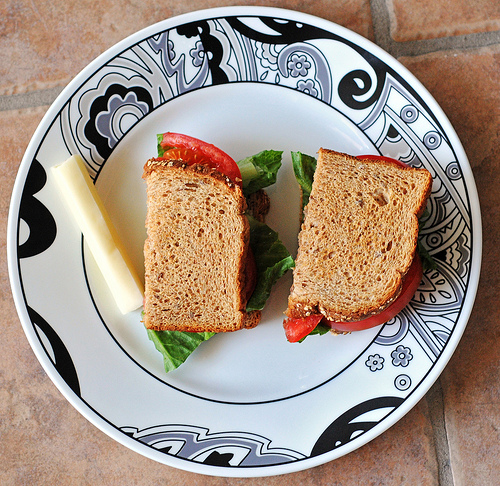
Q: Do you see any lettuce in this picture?
A: Yes, there is lettuce.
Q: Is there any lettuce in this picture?
A: Yes, there is lettuce.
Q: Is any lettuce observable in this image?
A: Yes, there is lettuce.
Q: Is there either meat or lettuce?
A: Yes, there is lettuce.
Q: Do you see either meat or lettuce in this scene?
A: Yes, there is lettuce.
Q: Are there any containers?
A: No, there are no containers.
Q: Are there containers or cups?
A: No, there are no containers or cups.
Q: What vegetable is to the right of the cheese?
A: The vegetable is lettuce.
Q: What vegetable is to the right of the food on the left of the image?
A: The vegetable is lettuce.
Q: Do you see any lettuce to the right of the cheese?
A: Yes, there is lettuce to the right of the cheese.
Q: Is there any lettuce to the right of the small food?
A: Yes, there is lettuce to the right of the cheese.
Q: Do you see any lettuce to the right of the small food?
A: Yes, there is lettuce to the right of the cheese.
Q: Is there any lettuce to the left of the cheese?
A: No, the lettuce is to the right of the cheese.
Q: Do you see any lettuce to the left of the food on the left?
A: No, the lettuce is to the right of the cheese.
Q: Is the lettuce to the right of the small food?
A: Yes, the lettuce is to the right of the cheese.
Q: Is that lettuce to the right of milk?
A: No, the lettuce is to the right of the cheese.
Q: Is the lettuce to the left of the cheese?
A: No, the lettuce is to the right of the cheese.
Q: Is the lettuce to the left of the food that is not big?
A: No, the lettuce is to the right of the cheese.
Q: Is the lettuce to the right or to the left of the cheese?
A: The lettuce is to the right of the cheese.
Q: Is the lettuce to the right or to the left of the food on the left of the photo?
A: The lettuce is to the right of the cheese.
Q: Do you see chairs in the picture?
A: No, there are no chairs.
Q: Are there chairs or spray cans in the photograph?
A: No, there are no chairs or spray cans.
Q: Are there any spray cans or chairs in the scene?
A: No, there are no chairs or spray cans.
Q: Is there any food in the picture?
A: Yes, there is food.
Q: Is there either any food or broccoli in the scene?
A: Yes, there is food.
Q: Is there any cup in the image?
A: No, there are no cups.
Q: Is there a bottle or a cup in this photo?
A: No, there are no cups or bottles.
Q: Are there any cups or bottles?
A: No, there are no cups or bottles.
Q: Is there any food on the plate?
A: Yes, there is food on the plate.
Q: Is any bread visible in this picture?
A: Yes, there is a bread.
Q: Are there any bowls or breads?
A: Yes, there is a bread.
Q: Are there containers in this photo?
A: No, there are no containers.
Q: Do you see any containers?
A: No, there are no containers.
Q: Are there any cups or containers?
A: No, there are no containers or cups.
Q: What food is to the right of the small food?
A: The food is a bread.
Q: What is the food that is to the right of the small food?
A: The food is a bread.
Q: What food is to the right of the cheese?
A: The food is a bread.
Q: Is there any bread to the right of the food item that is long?
A: Yes, there is a bread to the right of the cheese.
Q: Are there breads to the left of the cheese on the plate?
A: No, the bread is to the right of the cheese.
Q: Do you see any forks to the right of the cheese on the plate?
A: No, there is a bread to the right of the cheese.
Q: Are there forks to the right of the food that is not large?
A: No, there is a bread to the right of the cheese.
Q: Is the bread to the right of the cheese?
A: Yes, the bread is to the right of the cheese.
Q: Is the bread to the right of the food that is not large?
A: Yes, the bread is to the right of the cheese.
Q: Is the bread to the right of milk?
A: No, the bread is to the right of the cheese.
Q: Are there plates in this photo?
A: Yes, there is a plate.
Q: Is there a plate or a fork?
A: Yes, there is a plate.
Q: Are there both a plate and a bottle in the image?
A: No, there is a plate but no bottles.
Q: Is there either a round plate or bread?
A: Yes, there is a round plate.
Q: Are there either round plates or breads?
A: Yes, there is a round plate.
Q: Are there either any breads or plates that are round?
A: Yes, the plate is round.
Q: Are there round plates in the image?
A: Yes, there is a round plate.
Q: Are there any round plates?
A: Yes, there is a round plate.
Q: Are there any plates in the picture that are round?
A: Yes, there is a plate that is round.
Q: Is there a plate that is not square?
A: Yes, there is a round plate.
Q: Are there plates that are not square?
A: Yes, there is a round plate.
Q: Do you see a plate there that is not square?
A: Yes, there is a round plate.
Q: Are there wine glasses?
A: No, there are no wine glasses.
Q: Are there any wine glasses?
A: No, there are no wine glasses.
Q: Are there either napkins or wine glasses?
A: No, there are no wine glasses or napkins.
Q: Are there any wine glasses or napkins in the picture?
A: No, there are no wine glasses or napkins.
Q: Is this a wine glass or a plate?
A: This is a plate.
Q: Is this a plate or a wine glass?
A: This is a plate.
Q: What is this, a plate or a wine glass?
A: This is a plate.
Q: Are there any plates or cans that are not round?
A: No, there is a plate but it is round.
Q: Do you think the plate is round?
A: Yes, the plate is round.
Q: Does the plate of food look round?
A: Yes, the plate is round.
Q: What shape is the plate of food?
A: The plate is round.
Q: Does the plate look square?
A: No, the plate is round.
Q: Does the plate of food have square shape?
A: No, the plate is round.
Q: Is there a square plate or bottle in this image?
A: No, there is a plate but it is round.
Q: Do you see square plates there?
A: No, there is a plate but it is round.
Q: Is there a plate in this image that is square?
A: No, there is a plate but it is round.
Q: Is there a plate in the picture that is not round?
A: No, there is a plate but it is round.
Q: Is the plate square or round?
A: The plate is round.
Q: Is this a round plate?
A: Yes, this is a round plate.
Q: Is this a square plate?
A: No, this is a round plate.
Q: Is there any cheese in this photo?
A: Yes, there is cheese.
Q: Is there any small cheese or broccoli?
A: Yes, there is small cheese.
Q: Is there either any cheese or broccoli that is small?
A: Yes, the cheese is small.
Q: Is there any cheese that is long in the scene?
A: Yes, there is long cheese.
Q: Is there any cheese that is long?
A: Yes, there is cheese that is long.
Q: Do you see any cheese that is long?
A: Yes, there is cheese that is long.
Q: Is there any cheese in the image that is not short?
A: Yes, there is long cheese.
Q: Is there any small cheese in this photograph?
A: Yes, there is small cheese.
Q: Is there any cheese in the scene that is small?
A: Yes, there is cheese that is small.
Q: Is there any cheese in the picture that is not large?
A: Yes, there is small cheese.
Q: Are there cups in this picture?
A: No, there are no cups.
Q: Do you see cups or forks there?
A: No, there are no cups or forks.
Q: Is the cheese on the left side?
A: Yes, the cheese is on the left of the image.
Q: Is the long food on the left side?
A: Yes, the cheese is on the left of the image.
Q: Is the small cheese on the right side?
A: No, the cheese is on the left of the image.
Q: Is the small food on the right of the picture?
A: No, the cheese is on the left of the image.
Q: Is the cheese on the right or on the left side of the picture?
A: The cheese is on the left of the image.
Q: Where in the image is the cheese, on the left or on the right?
A: The cheese is on the left of the image.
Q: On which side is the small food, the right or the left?
A: The cheese is on the left of the image.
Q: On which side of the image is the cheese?
A: The cheese is on the left of the image.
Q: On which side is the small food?
A: The cheese is on the left of the image.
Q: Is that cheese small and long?
A: Yes, the cheese is small and long.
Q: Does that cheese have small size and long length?
A: Yes, the cheese is small and long.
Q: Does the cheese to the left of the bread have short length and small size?
A: No, the cheese is small but long.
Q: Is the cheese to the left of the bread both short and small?
A: No, the cheese is small but long.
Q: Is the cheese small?
A: Yes, the cheese is small.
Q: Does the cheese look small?
A: Yes, the cheese is small.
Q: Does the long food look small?
A: Yes, the cheese is small.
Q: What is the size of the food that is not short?
A: The cheese is small.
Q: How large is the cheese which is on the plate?
A: The cheese is small.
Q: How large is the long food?
A: The cheese is small.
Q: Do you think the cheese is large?
A: No, the cheese is small.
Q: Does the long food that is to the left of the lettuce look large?
A: No, the cheese is small.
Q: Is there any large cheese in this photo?
A: No, there is cheese but it is small.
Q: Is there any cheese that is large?
A: No, there is cheese but it is small.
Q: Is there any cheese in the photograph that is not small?
A: No, there is cheese but it is small.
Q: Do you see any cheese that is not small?
A: No, there is cheese but it is small.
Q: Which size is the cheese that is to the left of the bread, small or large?
A: The cheese is small.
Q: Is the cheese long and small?
A: Yes, the cheese is long and small.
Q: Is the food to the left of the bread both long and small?
A: Yes, the cheese is long and small.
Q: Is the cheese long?
A: Yes, the cheese is long.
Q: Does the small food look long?
A: Yes, the cheese is long.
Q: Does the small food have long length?
A: Yes, the cheese is long.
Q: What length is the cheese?
A: The cheese is long.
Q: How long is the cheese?
A: The cheese is long.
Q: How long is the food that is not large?
A: The cheese is long.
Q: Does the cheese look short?
A: No, the cheese is long.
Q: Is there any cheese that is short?
A: No, there is cheese but it is long.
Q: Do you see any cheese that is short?
A: No, there is cheese but it is long.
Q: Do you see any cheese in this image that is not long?
A: No, there is cheese but it is long.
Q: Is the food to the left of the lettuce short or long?
A: The cheese is long.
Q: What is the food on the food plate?
A: The food is cheese.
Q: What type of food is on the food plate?
A: The food is cheese.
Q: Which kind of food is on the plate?
A: The food is cheese.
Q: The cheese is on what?
A: The cheese is on the plate.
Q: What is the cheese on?
A: The cheese is on the plate.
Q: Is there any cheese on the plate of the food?
A: Yes, there is cheese on the plate.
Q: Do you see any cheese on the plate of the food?
A: Yes, there is cheese on the plate.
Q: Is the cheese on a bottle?
A: No, the cheese is on the plate.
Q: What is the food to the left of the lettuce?
A: The food is cheese.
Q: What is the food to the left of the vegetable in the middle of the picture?
A: The food is cheese.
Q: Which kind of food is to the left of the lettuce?
A: The food is cheese.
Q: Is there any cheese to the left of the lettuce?
A: Yes, there is cheese to the left of the lettuce.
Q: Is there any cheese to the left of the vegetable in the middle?
A: Yes, there is cheese to the left of the lettuce.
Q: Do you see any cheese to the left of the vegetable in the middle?
A: Yes, there is cheese to the left of the lettuce.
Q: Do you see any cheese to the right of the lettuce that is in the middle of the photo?
A: No, the cheese is to the left of the lettuce.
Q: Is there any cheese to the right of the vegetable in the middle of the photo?
A: No, the cheese is to the left of the lettuce.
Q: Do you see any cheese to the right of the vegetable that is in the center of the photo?
A: No, the cheese is to the left of the lettuce.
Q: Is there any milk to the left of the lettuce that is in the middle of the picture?
A: No, there is cheese to the left of the lettuce.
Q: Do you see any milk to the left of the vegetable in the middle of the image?
A: No, there is cheese to the left of the lettuce.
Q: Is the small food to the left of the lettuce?
A: Yes, the cheese is to the left of the lettuce.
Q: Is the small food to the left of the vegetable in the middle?
A: Yes, the cheese is to the left of the lettuce.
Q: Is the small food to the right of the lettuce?
A: No, the cheese is to the left of the lettuce.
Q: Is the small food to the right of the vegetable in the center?
A: No, the cheese is to the left of the lettuce.